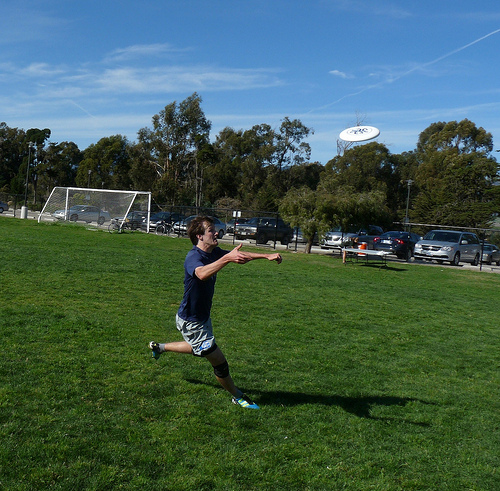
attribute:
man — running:
[149, 215, 284, 413]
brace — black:
[213, 360, 231, 377]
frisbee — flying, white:
[337, 124, 383, 146]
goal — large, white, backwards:
[37, 184, 154, 235]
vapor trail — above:
[298, 30, 498, 117]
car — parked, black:
[370, 228, 420, 258]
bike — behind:
[154, 218, 175, 237]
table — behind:
[339, 247, 389, 271]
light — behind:
[403, 176, 413, 238]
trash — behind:
[20, 204, 28, 221]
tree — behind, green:
[318, 144, 403, 246]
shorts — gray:
[171, 314, 217, 358]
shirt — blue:
[174, 246, 230, 322]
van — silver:
[414, 228, 483, 267]